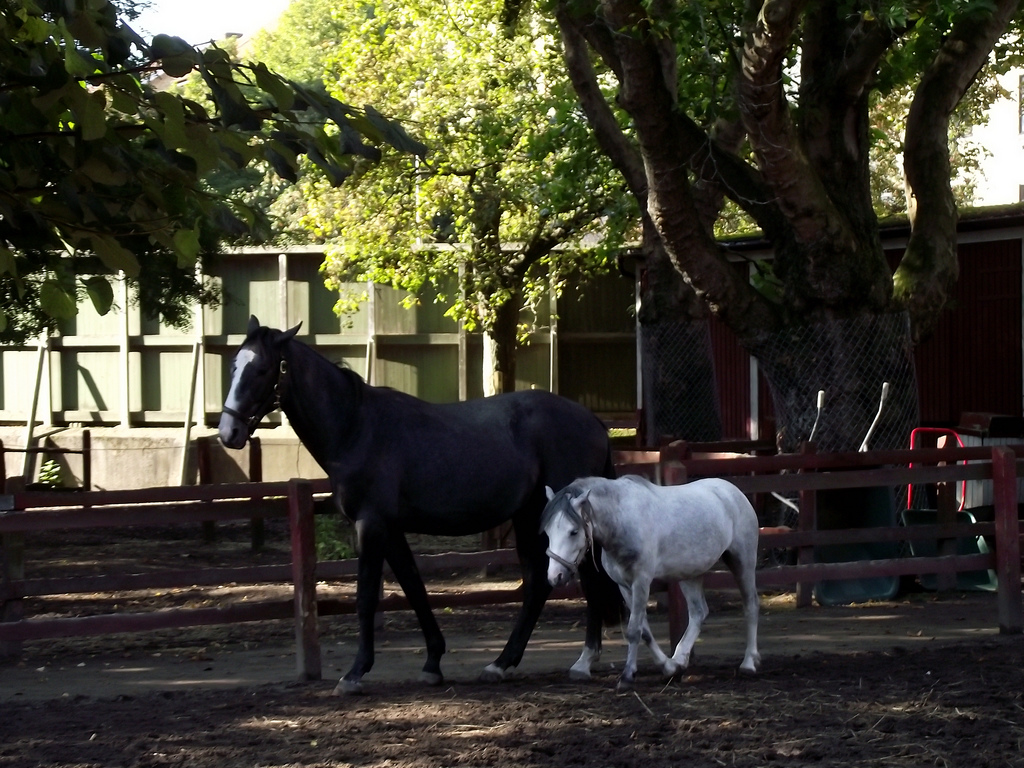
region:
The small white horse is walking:
[490, 414, 896, 700]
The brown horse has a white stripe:
[146, 203, 328, 558]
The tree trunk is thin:
[373, 13, 674, 437]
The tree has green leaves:
[216, 7, 608, 359]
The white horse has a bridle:
[494, 455, 634, 646]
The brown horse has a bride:
[171, 243, 350, 491]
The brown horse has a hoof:
[245, 588, 465, 734]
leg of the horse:
[728, 574, 757, 651]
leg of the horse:
[655, 610, 722, 642]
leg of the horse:
[608, 632, 644, 659]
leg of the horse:
[346, 607, 386, 664]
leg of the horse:
[412, 572, 447, 652]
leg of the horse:
[479, 598, 550, 644]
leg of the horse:
[582, 610, 637, 653]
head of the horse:
[191, 334, 287, 456]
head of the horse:
[516, 500, 602, 578]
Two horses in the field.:
[196, 322, 792, 708]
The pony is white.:
[521, 491, 804, 676]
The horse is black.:
[223, 322, 587, 678]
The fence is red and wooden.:
[46, 462, 449, 674]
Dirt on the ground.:
[351, 688, 751, 766]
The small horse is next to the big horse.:
[231, 344, 802, 706]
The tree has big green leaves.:
[29, 45, 286, 258]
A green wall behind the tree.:
[57, 231, 555, 463]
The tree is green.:
[319, 28, 646, 393]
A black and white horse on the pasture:
[213, 308, 621, 683]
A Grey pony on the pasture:
[532, 463, 768, 686]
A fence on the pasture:
[3, 439, 1022, 681]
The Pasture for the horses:
[19, 612, 1022, 764]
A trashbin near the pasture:
[948, 410, 1013, 532]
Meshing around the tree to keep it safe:
[629, 312, 735, 535]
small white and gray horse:
[541, 472, 760, 681]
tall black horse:
[215, 312, 621, 690]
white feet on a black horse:
[478, 641, 599, 680]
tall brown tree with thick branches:
[538, 12, 1014, 598]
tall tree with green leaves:
[150, 2, 676, 410]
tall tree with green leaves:
[0, 3, 434, 357]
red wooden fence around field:
[12, 432, 1022, 668]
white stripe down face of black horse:
[217, 341, 259, 449]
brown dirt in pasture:
[4, 634, 1020, 767]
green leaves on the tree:
[535, 136, 619, 279]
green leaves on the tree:
[500, 57, 558, 156]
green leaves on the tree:
[354, 31, 430, 139]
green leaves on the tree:
[438, 54, 516, 214]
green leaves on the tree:
[172, 72, 259, 162]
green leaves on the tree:
[254, 54, 414, 197]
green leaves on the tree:
[90, 113, 242, 270]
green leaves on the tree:
[626, 4, 713, 138]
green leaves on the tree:
[904, 51, 980, 135]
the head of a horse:
[509, 481, 608, 606]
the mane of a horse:
[544, 496, 596, 548]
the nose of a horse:
[541, 563, 579, 595]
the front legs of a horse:
[602, 555, 669, 677]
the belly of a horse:
[655, 540, 733, 598]